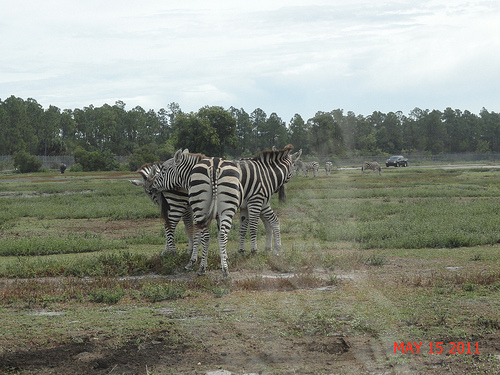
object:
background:
[0, 0, 500, 374]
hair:
[205, 195, 221, 243]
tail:
[197, 159, 226, 228]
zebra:
[150, 146, 243, 284]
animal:
[324, 161, 334, 175]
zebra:
[228, 143, 308, 259]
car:
[383, 154, 410, 168]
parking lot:
[376, 139, 500, 171]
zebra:
[358, 158, 385, 178]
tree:
[177, 110, 219, 162]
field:
[0, 165, 500, 374]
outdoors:
[0, 94, 500, 375]